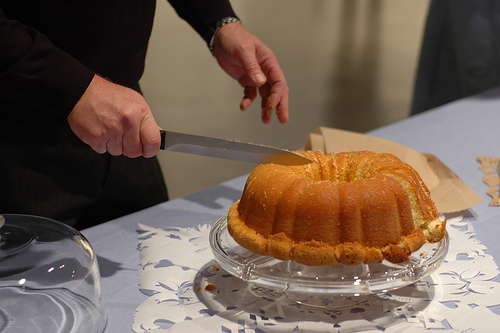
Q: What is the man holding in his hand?
A: A knife.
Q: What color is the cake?
A: Yellow.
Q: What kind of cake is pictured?
A: Bundt cake.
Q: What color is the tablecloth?
A: Light blue.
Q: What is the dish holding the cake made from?
A: Glass.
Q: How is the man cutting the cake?
A: With a knife.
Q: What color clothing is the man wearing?
A: Black.